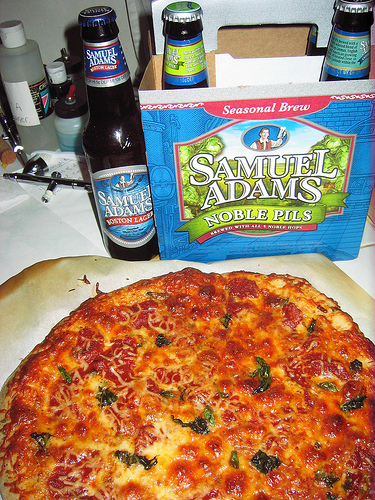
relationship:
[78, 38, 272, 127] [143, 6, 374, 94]
three bear bottles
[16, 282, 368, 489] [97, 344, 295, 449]
pizza has surface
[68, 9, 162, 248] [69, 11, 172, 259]
part of bottle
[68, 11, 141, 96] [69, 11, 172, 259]
neck of bottle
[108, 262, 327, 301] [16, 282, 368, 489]
edge of pizza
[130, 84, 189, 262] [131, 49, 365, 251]
edge of box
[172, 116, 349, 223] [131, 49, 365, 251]
surface of box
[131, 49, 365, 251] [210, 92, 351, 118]
box has red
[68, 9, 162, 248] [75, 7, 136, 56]
part of top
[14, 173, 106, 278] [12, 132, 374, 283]
part of desktop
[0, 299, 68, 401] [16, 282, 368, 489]
crust on pizza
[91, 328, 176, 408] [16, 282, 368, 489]
lines in pizza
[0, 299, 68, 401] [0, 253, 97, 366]
crust on paper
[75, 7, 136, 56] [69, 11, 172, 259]
top on beer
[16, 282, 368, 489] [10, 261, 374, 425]
pizza in box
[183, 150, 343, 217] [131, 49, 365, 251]
words on container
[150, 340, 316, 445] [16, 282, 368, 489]
cheese on pizza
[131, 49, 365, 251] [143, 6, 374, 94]
box of beer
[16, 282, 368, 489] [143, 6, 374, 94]
pizza near beer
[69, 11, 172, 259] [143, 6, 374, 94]
bottle of beer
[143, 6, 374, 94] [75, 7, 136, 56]
beer has top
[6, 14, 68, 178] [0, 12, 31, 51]
bottle with cap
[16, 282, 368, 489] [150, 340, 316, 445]
pizza has cheese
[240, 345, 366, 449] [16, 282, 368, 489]
vegetables on pizza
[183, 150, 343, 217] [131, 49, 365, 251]
letters on box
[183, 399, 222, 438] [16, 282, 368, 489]
basil on pizza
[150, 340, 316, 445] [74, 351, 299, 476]
cheese on tomatoes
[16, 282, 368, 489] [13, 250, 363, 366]
pizza on parchment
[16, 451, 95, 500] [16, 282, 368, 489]
pepper on pizza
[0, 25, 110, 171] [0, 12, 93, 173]
supplies being crafted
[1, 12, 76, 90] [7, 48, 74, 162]
caps on bottles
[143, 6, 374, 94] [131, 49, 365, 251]
beers in box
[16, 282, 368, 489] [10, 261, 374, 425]
pizza on box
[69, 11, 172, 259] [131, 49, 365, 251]
bottle near box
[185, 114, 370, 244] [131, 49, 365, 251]
picture on box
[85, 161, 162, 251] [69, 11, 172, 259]
sticker on bottle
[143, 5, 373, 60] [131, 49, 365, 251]
handle on box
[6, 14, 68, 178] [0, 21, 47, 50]
bottle has lid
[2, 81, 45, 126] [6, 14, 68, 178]
sticker on bottle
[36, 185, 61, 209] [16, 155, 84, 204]
tape over metal